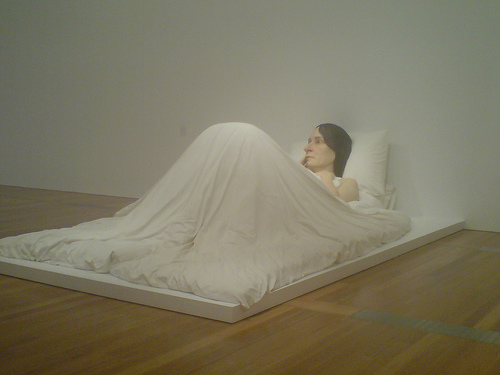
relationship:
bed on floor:
[5, 91, 474, 332] [225, 265, 385, 343]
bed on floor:
[93, 127, 402, 253] [24, 198, 289, 330]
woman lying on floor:
[295, 123, 359, 206] [83, 311, 214, 345]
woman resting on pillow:
[295, 123, 359, 206] [358, 137, 389, 192]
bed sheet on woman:
[1, 121, 409, 311] [295, 123, 359, 206]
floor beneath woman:
[0, 228, 499, 375] [295, 123, 359, 206]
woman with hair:
[295, 123, 359, 206] [315, 123, 353, 178]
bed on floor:
[0, 209, 467, 322] [0, 228, 499, 375]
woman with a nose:
[295, 123, 359, 206] [302, 144, 314, 153]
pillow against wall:
[283, 129, 391, 197] [2, 0, 498, 234]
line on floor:
[292, 296, 499, 344] [0, 228, 499, 375]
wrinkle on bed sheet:
[116, 120, 256, 237] [1, 121, 409, 311]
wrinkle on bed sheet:
[147, 134, 216, 231] [1, 121, 409, 311]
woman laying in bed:
[295, 123, 359, 206] [2, 119, 464, 320]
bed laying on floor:
[5, 91, 474, 332] [0, 228, 499, 375]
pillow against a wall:
[283, 129, 391, 197] [2, 0, 498, 234]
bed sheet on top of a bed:
[1, 121, 409, 311] [2, 119, 464, 320]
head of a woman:
[304, 122, 352, 172] [291, 118, 357, 207]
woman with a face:
[295, 123, 359, 206] [302, 124, 336, 167]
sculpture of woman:
[0, 119, 466, 323] [295, 123, 359, 206]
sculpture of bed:
[0, 119, 466, 323] [0, 212, 465, 323]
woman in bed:
[295, 123, 359, 206] [0, 212, 465, 323]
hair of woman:
[317, 120, 354, 179] [285, 122, 360, 204]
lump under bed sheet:
[137, 123, 345, 259] [1, 121, 409, 311]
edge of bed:
[0, 256, 236, 324] [0, 209, 467, 322]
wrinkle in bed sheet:
[116, 187, 191, 237] [4, 121, 409, 311]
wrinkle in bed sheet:
[116, 120, 256, 237] [4, 121, 409, 311]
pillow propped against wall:
[283, 129, 391, 197] [2, 0, 498, 234]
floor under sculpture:
[0, 228, 499, 375] [0, 119, 466, 323]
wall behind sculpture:
[2, 0, 498, 234] [0, 119, 466, 323]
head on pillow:
[304, 122, 352, 172] [290, 124, 392, 213]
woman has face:
[295, 121, 363, 206] [304, 125, 326, 167]